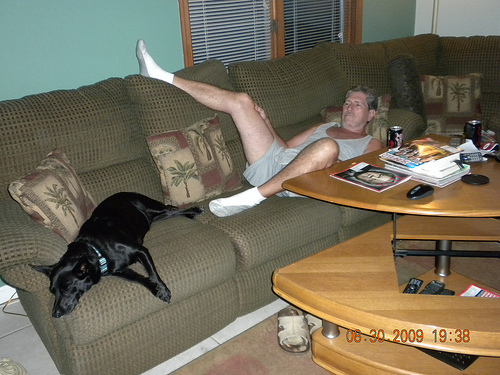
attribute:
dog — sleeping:
[30, 190, 205, 316]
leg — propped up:
[136, 39, 281, 176]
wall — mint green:
[0, 0, 133, 73]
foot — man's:
[128, 30, 188, 96]